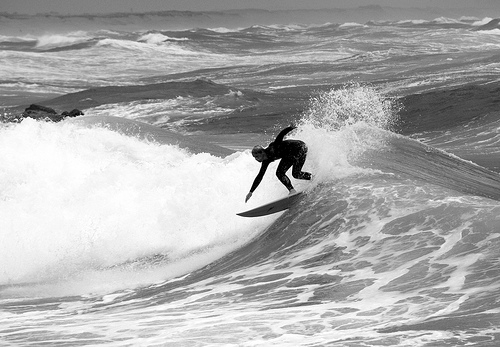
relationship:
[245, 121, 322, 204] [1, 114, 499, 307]
man on wave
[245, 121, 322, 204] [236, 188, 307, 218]
man on surfboard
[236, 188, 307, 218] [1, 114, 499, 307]
surfboard on wave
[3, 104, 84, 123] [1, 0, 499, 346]
rocks coming out of water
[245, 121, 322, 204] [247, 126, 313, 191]
man wearing wetsuit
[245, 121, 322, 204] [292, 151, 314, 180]
man has leg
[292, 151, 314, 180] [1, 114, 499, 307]
leg in wave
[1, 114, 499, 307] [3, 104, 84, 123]
wave crashing into rocks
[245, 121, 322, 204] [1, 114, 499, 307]
man riding wave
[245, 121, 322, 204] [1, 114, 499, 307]
man on top of wave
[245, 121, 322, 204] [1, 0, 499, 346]
man in water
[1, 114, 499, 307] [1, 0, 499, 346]
wave in water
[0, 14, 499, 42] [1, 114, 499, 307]
waves behind wave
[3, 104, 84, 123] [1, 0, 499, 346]
rocks in water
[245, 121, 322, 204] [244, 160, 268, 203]
man has arm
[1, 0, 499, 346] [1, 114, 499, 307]
water has wave